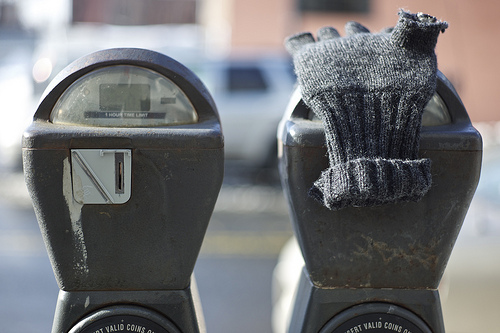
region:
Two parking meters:
[10, 16, 478, 327]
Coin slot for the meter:
[100, 148, 145, 206]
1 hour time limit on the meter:
[95, 104, 165, 120]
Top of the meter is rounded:
[27, 45, 218, 116]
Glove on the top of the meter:
[276, 16, 483, 208]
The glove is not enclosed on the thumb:
[394, 3, 450, 40]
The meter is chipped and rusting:
[319, 224, 451, 290]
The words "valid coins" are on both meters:
[89, 301, 415, 331]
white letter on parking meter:
[104, 323, 111, 331]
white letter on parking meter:
[108, 324, 114, 331]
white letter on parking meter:
[118, 323, 125, 330]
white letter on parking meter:
[126, 322, 131, 330]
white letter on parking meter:
[128, 323, 138, 331]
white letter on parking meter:
[134, 324, 142, 331]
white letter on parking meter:
[351, 325, 358, 332]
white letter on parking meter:
[355, 322, 365, 332]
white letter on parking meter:
[361, 320, 369, 330]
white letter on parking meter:
[376, 320, 384, 329]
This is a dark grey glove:
[336, 34, 425, 218]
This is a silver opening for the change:
[63, 124, 137, 187]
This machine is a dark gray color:
[58, 59, 153, 251]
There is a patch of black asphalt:
[228, 278, 243, 308]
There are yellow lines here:
[231, 226, 260, 298]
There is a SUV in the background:
[233, 50, 283, 156]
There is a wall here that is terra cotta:
[468, 20, 488, 66]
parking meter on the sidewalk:
[19, 21, 219, 332]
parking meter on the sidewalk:
[19, 30, 225, 325]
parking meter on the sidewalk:
[13, 51, 236, 326]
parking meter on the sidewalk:
[15, 45, 227, 332]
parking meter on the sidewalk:
[12, 38, 233, 319]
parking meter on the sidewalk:
[22, 42, 242, 328]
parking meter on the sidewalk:
[11, 47, 231, 332]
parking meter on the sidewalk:
[16, 43, 223, 330]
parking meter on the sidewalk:
[13, 51, 278, 331]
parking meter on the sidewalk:
[2, 43, 239, 332]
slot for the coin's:
[98, 146, 135, 206]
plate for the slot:
[53, 140, 138, 211]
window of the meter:
[38, 55, 213, 127]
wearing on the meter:
[54, 153, 86, 292]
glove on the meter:
[275, 0, 455, 236]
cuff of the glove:
[270, 150, 441, 210]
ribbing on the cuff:
[280, 76, 445, 198]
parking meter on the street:
[0, 45, 230, 327]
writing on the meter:
[77, 322, 160, 330]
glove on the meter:
[286, 13, 467, 207]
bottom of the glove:
[281, 137, 448, 219]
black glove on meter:
[282, 74, 442, 210]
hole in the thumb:
[378, 0, 458, 58]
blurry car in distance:
[204, 24, 287, 139]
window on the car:
[216, 60, 271, 111]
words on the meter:
[88, 78, 170, 129]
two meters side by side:
[28, 19, 470, 294]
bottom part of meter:
[273, 238, 467, 331]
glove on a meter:
[272, 15, 447, 217]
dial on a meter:
[334, 295, 423, 332]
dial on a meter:
[70, 305, 169, 331]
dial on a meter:
[70, 81, 192, 126]